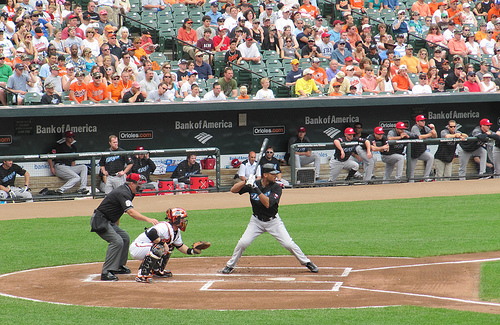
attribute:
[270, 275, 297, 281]
plate — white, home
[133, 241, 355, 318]
lines — chalk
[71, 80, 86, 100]
shirt — orange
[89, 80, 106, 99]
shirt — orange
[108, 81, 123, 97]
shirt — orange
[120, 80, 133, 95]
shirt — orange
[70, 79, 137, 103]
shirts — orange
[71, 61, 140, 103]
men — four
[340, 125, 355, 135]
baseball cap — red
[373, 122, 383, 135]
baseball cap — red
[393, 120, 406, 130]
baseball cap — red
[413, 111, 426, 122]
baseball cap — red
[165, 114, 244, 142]
letters — white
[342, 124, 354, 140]
ball cap — red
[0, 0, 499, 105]
crowd — large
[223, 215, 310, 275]
pants — gray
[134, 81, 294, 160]
sign — Bank of America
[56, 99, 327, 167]
logo — bank of america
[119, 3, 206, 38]
seats — empty, green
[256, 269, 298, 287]
plate — home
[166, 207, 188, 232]
mask — protective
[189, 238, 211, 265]
mit — baseball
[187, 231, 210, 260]
hand — catcher's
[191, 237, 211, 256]
mitt — baseball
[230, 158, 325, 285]
player — baseball, in batting stance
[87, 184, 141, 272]
uniform — umpire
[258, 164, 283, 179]
helmet — black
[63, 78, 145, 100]
shirts — orange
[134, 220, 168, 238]
back — catcher's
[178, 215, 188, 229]
face — catcher's